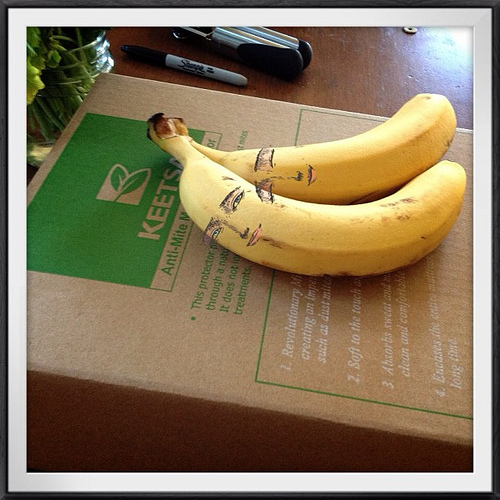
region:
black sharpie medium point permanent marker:
[122, 40, 269, 106]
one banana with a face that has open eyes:
[144, 156, 465, 302]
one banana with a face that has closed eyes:
[204, 96, 453, 203]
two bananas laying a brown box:
[56, 113, 465, 378]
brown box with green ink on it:
[34, 124, 371, 415]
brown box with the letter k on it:
[87, 114, 257, 359]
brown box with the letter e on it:
[80, 113, 287, 360]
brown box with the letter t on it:
[80, 122, 249, 332]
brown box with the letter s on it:
[75, 118, 276, 363]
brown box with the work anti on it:
[72, 228, 329, 398]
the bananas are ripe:
[210, 188, 459, 291]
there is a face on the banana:
[206, 201, 278, 256]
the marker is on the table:
[151, 46, 220, 75]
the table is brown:
[384, 53, 475, 82]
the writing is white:
[280, 310, 459, 367]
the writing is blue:
[182, 278, 252, 321]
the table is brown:
[106, 314, 203, 392]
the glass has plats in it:
[28, 53, 123, 98]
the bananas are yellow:
[181, 147, 466, 244]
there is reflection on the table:
[389, 43, 471, 80]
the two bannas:
[168, 108, 464, 307]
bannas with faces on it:
[205, 181, 321, 268]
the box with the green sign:
[77, 116, 184, 334]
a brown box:
[72, 284, 237, 425]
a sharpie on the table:
[156, 47, 261, 89]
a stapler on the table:
[153, 3, 356, 79]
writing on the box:
[232, 318, 432, 409]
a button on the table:
[395, 27, 429, 51]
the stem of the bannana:
[136, 106, 218, 188]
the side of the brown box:
[93, 406, 262, 478]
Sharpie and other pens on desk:
[107, 20, 322, 92]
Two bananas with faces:
[108, 82, 472, 332]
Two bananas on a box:
[68, 54, 469, 449]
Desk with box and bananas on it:
[44, 70, 452, 485]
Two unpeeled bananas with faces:
[72, 64, 497, 321]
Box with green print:
[27, 48, 455, 432]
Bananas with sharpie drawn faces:
[68, 45, 450, 399]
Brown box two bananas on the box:
[34, 64, 484, 441]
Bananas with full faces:
[97, 100, 479, 267]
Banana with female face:
[144, 104, 458, 369]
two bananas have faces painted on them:
[187, 141, 325, 254]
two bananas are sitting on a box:
[30, 73, 470, 465]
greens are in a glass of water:
[30, 30, 115, 147]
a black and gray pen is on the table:
[115, 37, 250, 92]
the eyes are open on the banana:
[196, 185, 261, 255]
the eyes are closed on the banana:
[248, 143, 318, 204]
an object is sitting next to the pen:
[167, 22, 310, 82]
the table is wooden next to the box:
[96, 23, 476, 139]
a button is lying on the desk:
[400, 25, 421, 40]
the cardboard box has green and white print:
[35, 70, 471, 469]